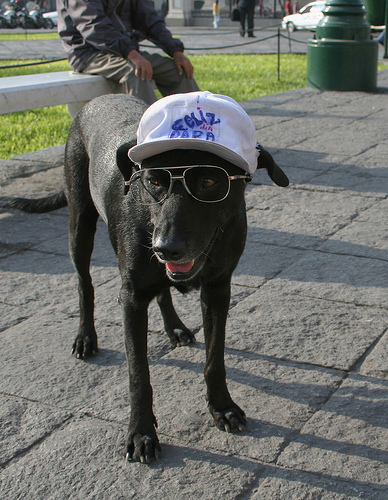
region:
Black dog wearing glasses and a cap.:
[61, 90, 290, 466]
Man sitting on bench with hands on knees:
[56, 0, 198, 102]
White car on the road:
[280, 0, 324, 36]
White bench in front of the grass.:
[0, 66, 127, 113]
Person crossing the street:
[233, 1, 258, 41]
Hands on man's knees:
[130, 41, 196, 85]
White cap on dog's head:
[126, 88, 258, 170]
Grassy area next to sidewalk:
[1, 51, 309, 146]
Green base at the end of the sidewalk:
[305, 0, 379, 93]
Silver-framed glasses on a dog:
[122, 160, 249, 205]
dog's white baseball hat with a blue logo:
[126, 88, 259, 170]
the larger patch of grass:
[0, 50, 387, 157]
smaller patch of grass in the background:
[0, 29, 178, 35]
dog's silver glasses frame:
[121, 163, 248, 202]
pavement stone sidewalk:
[0, 61, 385, 494]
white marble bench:
[0, 67, 126, 115]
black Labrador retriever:
[1, 90, 289, 464]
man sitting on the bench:
[56, 0, 202, 106]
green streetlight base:
[305, 0, 378, 90]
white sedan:
[281, 0, 326, 32]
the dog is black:
[57, 61, 259, 320]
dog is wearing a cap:
[91, 101, 283, 191]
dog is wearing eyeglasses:
[115, 161, 240, 225]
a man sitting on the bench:
[60, 1, 203, 112]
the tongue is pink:
[159, 242, 197, 288]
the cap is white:
[101, 96, 285, 193]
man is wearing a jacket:
[47, 9, 244, 66]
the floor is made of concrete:
[261, 222, 347, 498]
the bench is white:
[39, 49, 220, 122]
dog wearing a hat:
[103, 61, 251, 188]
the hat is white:
[106, 59, 225, 157]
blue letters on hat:
[133, 62, 231, 151]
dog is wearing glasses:
[131, 163, 244, 231]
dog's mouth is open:
[145, 226, 212, 286]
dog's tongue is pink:
[129, 234, 197, 280]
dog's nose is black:
[138, 225, 196, 262]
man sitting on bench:
[52, 0, 212, 92]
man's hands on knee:
[111, 16, 216, 89]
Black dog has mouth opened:
[6, 90, 290, 465]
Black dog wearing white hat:
[11, 82, 293, 465]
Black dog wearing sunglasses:
[9, 91, 292, 470]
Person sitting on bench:
[55, 0, 204, 109]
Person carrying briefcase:
[227, 0, 260, 36]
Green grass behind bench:
[0, 48, 387, 159]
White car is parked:
[278, 2, 321, 35]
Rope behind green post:
[0, 27, 304, 105]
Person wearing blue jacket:
[52, 0, 199, 100]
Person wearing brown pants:
[58, 0, 201, 108]